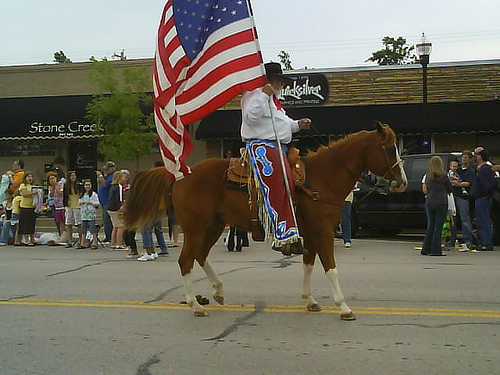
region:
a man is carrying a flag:
[147, 26, 457, 214]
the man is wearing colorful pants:
[210, 137, 429, 303]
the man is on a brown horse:
[180, 146, 477, 262]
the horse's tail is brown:
[123, 161, 231, 308]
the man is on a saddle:
[226, 137, 469, 206]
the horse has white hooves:
[175, 266, 284, 353]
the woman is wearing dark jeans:
[410, 177, 460, 372]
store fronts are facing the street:
[28, 113, 488, 255]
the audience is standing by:
[30, 160, 197, 323]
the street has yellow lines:
[81, 283, 193, 330]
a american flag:
[118, 3, 312, 153]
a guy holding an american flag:
[150, 6, 335, 153]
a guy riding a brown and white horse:
[114, 15, 406, 336]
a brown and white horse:
[117, 125, 440, 320]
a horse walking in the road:
[123, 122, 424, 356]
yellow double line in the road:
[374, 285, 496, 332]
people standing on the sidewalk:
[6, 141, 180, 256]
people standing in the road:
[411, 130, 498, 270]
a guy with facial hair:
[250, 52, 300, 109]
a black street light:
[392, 13, 444, 158]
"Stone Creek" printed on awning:
[28, 118, 108, 139]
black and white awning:
[1, 94, 161, 139]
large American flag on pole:
[155, 1, 270, 181]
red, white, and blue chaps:
[246, 134, 309, 260]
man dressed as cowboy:
[234, 55, 314, 264]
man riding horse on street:
[114, 57, 410, 322]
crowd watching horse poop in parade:
[2, 155, 157, 253]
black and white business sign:
[274, 72, 331, 109]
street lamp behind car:
[413, 30, 435, 155]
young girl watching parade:
[75, 176, 102, 253]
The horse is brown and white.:
[82, 107, 423, 347]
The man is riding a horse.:
[119, 0, 418, 335]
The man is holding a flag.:
[150, 0, 420, 345]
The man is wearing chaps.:
[145, 1, 424, 334]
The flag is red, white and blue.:
[144, 3, 315, 265]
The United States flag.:
[144, 0, 317, 266]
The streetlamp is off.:
[404, 27, 437, 157]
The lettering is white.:
[26, 116, 38, 136]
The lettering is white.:
[66, 119, 78, 133]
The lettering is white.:
[37, 117, 44, 135]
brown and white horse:
[126, 123, 407, 318]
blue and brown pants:
[246, 138, 302, 246]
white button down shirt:
[242, 88, 299, 145]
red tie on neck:
[272, 94, 282, 112]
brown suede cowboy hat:
[263, 63, 295, 82]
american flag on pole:
[151, 0, 264, 182]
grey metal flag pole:
[266, 84, 303, 242]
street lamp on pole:
[417, 33, 431, 152]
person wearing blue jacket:
[109, 170, 126, 249]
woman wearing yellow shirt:
[18, 170, 43, 245]